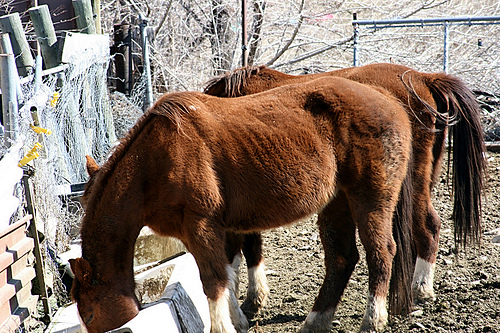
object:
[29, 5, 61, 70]
pipe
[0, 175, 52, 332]
fence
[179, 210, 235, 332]
leg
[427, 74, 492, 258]
tail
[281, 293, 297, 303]
rocks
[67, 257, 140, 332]
head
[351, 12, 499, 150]
metal fencing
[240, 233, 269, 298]
leg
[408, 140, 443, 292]
leg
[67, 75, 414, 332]
horse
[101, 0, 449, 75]
trees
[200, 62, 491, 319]
horse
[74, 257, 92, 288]
ear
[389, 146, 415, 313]
tail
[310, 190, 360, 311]
leg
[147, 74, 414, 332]
body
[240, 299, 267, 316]
foot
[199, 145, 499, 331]
ground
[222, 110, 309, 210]
fur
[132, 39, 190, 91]
branches